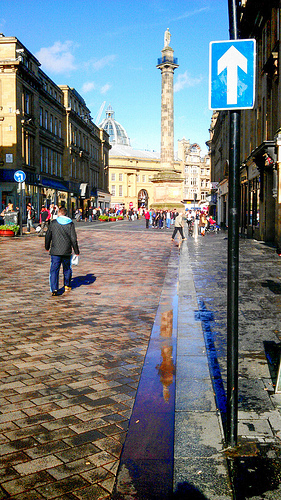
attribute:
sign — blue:
[207, 38, 255, 109]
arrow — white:
[217, 44, 247, 103]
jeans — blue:
[47, 253, 71, 291]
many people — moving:
[1, 201, 280, 294]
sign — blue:
[12, 169, 27, 182]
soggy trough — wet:
[133, 241, 180, 498]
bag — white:
[69, 253, 79, 265]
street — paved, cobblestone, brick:
[0, 217, 181, 498]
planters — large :
[117, 216, 123, 222]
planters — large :
[107, 217, 115, 222]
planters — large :
[97, 217, 107, 221]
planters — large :
[0, 229, 13, 237]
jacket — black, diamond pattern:
[45, 215, 79, 255]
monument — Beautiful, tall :
[148, 24, 182, 214]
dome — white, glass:
[92, 100, 133, 152]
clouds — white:
[36, 36, 114, 100]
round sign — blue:
[11, 168, 28, 183]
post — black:
[216, 91, 250, 317]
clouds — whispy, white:
[38, 34, 126, 79]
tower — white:
[151, 18, 182, 173]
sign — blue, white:
[208, 54, 258, 107]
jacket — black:
[42, 216, 81, 256]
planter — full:
[0, 229, 14, 236]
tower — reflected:
[135, 16, 190, 213]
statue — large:
[161, 25, 173, 50]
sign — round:
[7, 165, 29, 184]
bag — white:
[67, 252, 83, 265]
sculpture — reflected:
[159, 382, 174, 411]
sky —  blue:
[2, 0, 230, 159]